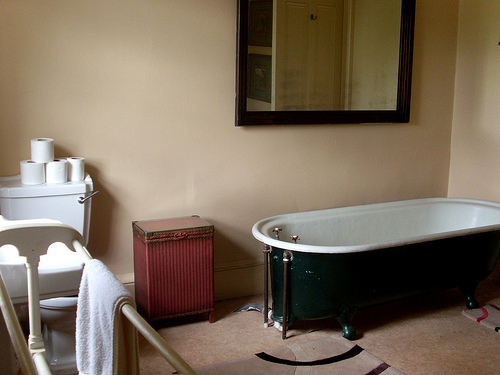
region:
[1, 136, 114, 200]
The four rolls of toilet paper sits on the toilet.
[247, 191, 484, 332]
The tub is green.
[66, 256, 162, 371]
A white towel is hanging from the rack.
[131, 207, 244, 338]
A red hamper sits next to the toilet.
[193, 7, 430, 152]
A mirror is on the wall.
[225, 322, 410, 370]
A mat is on the floor.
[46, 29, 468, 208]
The walls are beige.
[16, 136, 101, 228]
The toilet paper is white.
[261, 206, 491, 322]
The tub is white in the inside.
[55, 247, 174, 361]
The towel is white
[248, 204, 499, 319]
Dark green bathtub with legs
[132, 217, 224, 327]
Maroon hamper with lid.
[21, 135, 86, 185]
Four toilet paper rolls.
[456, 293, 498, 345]
One small towel.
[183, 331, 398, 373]
Large bath rug with circular lines.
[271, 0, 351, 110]
Door in the mirror.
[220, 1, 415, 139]
Large mirror on the wall.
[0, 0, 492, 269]
Cream colored wall.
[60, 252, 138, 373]
Large towel hanging from rod.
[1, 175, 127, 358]
White toilet with handle.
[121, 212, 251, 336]
The close hamper is a reddish color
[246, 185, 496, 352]
The bathtub is old fashioned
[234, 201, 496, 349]
The bathtub doesn't have a shower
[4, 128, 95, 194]
4 rolls of toilet paper on the lid of the tank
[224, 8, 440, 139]
A large mirror on the wall of the bathroom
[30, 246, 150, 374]
A towel hanging on a wooden rack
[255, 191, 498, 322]
The bathtub is painted green on the outside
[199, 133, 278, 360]
The walls and floor are the same color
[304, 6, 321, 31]
there is a hook on the back of the door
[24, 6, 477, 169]
The mirror is the only decoration on the wall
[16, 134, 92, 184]
four toilet paper rolls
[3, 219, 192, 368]
white towel on towel rack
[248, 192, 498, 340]
green and white old claw foot tub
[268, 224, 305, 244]
hot and cold faucets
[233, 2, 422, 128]
mirror with wood frame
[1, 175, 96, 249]
toilet tank and flush handle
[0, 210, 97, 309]
pedestal sink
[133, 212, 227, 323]
red clothes hamper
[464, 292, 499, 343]
white red and black towel mat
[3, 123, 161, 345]
toilet and towel and bathroom sink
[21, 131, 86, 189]
Four rolls of toilet paper on the back of the toilet.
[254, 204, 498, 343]
A claw foot white bathtub in the corner of the bathroom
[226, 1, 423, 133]
a dark rimmed mirror on the bathroom wall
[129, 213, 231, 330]
a burgandy clothes hamper in the bathroom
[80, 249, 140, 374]
a white towel hanging in a towel rack in the bathrom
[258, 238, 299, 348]
Two pipes from the bathroom floor into the bathtub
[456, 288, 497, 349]
A tan rug with red and black stripes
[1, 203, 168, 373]
An off white towel rack in the bathroom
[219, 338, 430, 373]
A tan rug with black stripes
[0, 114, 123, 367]
A white toilet in the bathroom